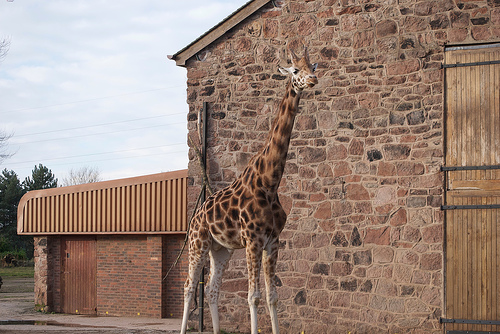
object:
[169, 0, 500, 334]
walls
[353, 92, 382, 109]
stone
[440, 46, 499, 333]
door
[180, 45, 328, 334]
giraffe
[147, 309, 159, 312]
bricks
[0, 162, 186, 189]
electrical lines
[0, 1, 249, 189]
sky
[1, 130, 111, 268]
trees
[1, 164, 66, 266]
leaves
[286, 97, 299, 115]
horns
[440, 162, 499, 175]
latch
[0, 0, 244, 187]
clouds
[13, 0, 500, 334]
building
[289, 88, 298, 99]
spot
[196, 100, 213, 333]
pole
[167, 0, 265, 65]
roof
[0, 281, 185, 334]
ground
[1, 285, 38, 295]
dirt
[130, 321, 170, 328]
water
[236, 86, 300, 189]
neck